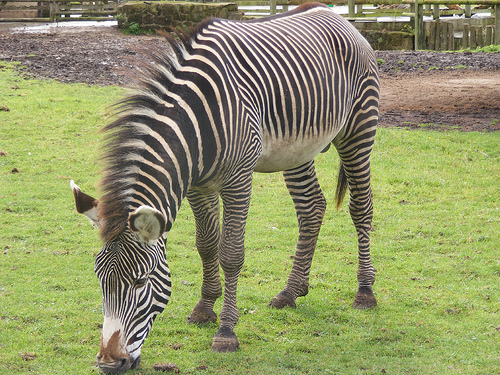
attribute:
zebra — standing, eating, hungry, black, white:
[69, 3, 384, 373]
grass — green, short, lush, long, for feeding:
[3, 60, 500, 371]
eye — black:
[134, 277, 148, 288]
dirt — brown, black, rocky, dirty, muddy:
[0, 10, 499, 132]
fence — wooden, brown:
[416, 12, 500, 53]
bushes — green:
[117, 4, 230, 32]